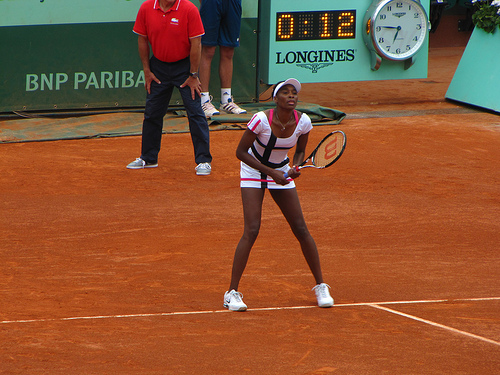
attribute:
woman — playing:
[210, 83, 406, 338]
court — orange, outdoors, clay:
[1, 190, 222, 374]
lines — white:
[273, 296, 492, 354]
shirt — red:
[122, 1, 207, 66]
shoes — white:
[217, 275, 344, 315]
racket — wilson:
[284, 127, 345, 174]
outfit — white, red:
[227, 100, 322, 217]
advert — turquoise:
[268, 38, 430, 80]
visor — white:
[276, 76, 304, 96]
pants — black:
[149, 63, 206, 166]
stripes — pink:
[235, 129, 298, 186]